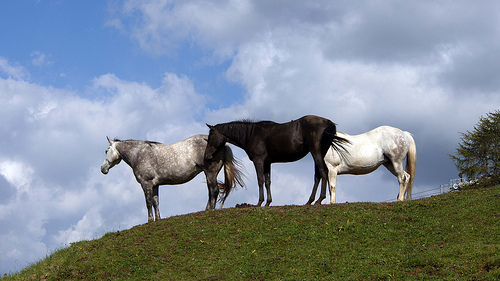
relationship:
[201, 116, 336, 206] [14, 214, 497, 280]
horse standing on a hill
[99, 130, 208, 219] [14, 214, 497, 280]
horse standing on a hill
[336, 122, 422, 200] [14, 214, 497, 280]
horse standing on a hill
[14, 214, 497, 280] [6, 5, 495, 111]
hill with cloudy sky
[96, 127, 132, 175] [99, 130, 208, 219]
head of gray horse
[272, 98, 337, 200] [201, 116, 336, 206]
back end of black horse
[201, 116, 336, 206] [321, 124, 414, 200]
horse between horse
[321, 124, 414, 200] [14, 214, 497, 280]
horse on hilltop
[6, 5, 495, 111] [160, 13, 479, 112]
sky has clouds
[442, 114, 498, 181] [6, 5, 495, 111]
tree in background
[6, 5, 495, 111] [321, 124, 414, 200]
cloudy sky above horse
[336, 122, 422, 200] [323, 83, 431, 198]
horse in back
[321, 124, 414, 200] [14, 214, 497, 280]
horse standing on a hill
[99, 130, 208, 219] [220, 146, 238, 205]
horse has tail